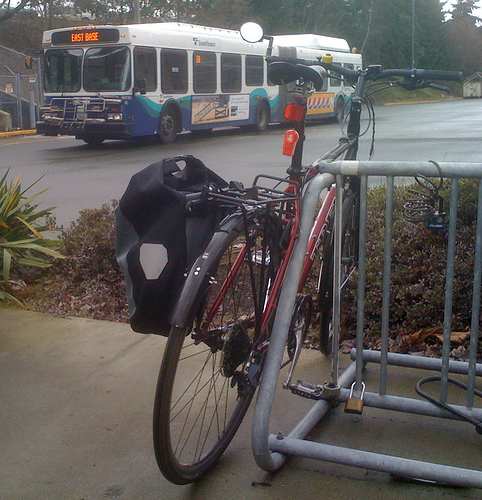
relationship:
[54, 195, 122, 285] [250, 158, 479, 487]
shrubs behind bars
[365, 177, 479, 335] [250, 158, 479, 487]
shrubs behind bars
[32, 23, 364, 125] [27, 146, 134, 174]
bus sitting on paved area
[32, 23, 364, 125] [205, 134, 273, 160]
bus sitting on paved area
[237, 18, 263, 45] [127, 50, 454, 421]
bicycle mirror on bike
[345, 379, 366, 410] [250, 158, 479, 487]
lock on bars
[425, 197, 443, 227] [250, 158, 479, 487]
lock on bars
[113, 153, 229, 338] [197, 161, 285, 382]
back pack on bike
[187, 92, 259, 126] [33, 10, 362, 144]
billboard on side of bus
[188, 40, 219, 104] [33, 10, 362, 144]
windows on bus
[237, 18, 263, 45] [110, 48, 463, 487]
bicycle mirror on bicycle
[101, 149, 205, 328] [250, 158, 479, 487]
back pack attached on bars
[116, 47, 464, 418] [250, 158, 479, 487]
bicycle chained to bars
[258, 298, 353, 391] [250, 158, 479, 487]
chain on a bars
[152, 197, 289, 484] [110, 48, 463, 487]
rear wheel on a bicycle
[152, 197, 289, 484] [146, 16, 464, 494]
rear wheel on a bicycle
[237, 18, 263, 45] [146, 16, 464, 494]
bicycle mirror on bicycle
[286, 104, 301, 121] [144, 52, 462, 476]
reflector on bicycle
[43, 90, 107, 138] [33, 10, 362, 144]
bikerack of bus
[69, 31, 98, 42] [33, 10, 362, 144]
bus sign on bus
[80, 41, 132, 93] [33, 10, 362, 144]
window on bus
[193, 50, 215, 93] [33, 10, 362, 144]
window on bus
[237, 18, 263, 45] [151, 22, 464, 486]
bicycle mirror on bicycle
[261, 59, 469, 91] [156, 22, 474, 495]
bike handle on bike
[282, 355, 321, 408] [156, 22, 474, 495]
pedal on bike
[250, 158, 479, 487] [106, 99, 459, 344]
bars with a bike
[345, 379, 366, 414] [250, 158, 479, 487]
lock attached to bars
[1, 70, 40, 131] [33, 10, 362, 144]
fence to left of bus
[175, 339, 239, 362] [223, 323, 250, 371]
spoke and gears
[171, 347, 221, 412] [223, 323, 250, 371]
spoke and gears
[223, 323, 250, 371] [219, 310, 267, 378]
gears with chain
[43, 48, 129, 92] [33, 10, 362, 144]
windshield of a bus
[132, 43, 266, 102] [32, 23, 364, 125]
windows on a bus